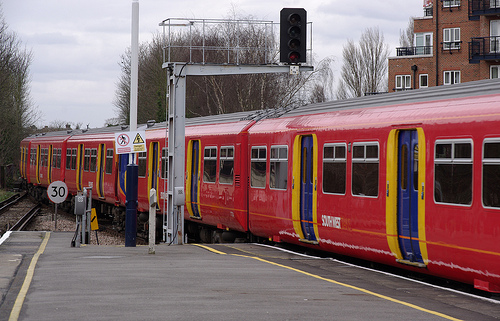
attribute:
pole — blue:
[126, 152, 139, 246]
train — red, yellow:
[179, 85, 499, 257]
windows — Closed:
[249, 143, 289, 193]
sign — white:
[111, 128, 148, 155]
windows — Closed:
[346, 139, 381, 200]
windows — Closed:
[427, 137, 474, 207]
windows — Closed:
[248, 137, 267, 192]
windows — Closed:
[220, 141, 234, 177]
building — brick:
[383, 2, 497, 89]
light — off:
[251, 11, 341, 82]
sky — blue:
[50, 24, 160, 83]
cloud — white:
[2, 24, 92, 46]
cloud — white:
[81, 7, 241, 44]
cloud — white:
[297, 4, 428, 49]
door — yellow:
[374, 112, 446, 287]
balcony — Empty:
[380, 23, 453, 83]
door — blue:
[386, 125, 431, 269]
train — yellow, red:
[245, 84, 499, 279]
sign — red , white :
[47, 179, 69, 202]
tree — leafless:
[142, 29, 243, 96]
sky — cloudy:
[35, 28, 92, 93]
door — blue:
[370, 116, 454, 271]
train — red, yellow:
[19, 81, 496, 292]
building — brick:
[378, 30, 499, 90]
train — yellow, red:
[299, 155, 419, 199]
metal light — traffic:
[148, 5, 313, 250]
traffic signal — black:
[277, 2, 314, 69]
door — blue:
[187, 137, 202, 219]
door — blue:
[393, 125, 423, 262]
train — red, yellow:
[184, 126, 256, 229]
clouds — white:
[23, 17, 136, 93]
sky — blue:
[3, 1, 433, 124]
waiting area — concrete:
[4, 225, 474, 319]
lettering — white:
[319, 212, 343, 227]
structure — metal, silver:
[156, 18, 314, 246]